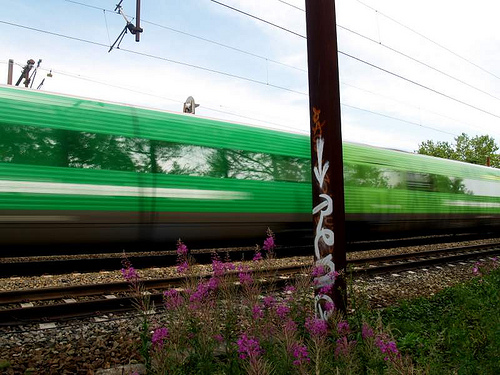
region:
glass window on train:
[6, 123, 68, 168]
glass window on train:
[62, 128, 153, 176]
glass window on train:
[151, 136, 220, 179]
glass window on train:
[225, 150, 272, 180]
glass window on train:
[268, 150, 308, 182]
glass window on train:
[341, 163, 381, 187]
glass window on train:
[372, 164, 404, 188]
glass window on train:
[399, 170, 433, 190]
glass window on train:
[429, 174, 467, 193]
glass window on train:
[469, 178, 496, 195]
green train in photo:
[101, 113, 247, 202]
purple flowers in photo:
[156, 251, 312, 361]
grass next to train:
[420, 285, 477, 330]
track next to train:
[38, 252, 125, 342]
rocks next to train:
[59, 317, 121, 363]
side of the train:
[117, 130, 243, 195]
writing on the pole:
[305, 105, 346, 277]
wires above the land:
[180, 5, 265, 80]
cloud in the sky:
[229, 3, 286, 44]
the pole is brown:
[283, 33, 389, 374]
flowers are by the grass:
[122, 263, 286, 343]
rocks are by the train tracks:
[51, 268, 96, 337]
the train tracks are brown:
[66, 246, 143, 355]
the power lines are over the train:
[106, 8, 415, 207]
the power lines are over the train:
[10, 50, 115, 130]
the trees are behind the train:
[417, 130, 495, 164]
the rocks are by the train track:
[364, 259, 461, 292]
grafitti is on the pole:
[300, 118, 356, 372]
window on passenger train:
[2, 110, 67, 170]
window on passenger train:
[53, 119, 150, 181]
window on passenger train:
[143, 129, 225, 181]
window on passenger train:
[216, 143, 285, 186]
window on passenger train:
[264, 143, 314, 185]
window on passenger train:
[394, 162, 436, 199]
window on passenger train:
[431, 165, 474, 200]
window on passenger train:
[466, 175, 497, 207]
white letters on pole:
[293, 128, 356, 326]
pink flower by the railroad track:
[235, 328, 253, 360]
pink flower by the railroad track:
[306, 316, 322, 337]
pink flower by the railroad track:
[334, 317, 357, 339]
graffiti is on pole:
[309, 131, 336, 324]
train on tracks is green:
[2, 85, 499, 252]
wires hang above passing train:
[0, 0, 499, 146]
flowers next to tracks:
[97, 228, 403, 372]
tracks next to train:
[0, 238, 499, 329]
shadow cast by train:
[0, 231, 499, 278]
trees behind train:
[411, 130, 499, 165]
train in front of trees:
[2, 83, 499, 253]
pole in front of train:
[303, 0, 353, 327]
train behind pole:
[0, 82, 499, 256]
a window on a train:
[70, 130, 152, 178]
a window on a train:
[156, 140, 224, 182]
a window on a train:
[226, 142, 273, 179]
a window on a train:
[269, 147, 308, 182]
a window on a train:
[343, 161, 375, 190]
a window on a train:
[369, 165, 401, 189]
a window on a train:
[403, 172, 432, 192]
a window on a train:
[428, 168, 453, 198]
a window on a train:
[448, 173, 469, 196]